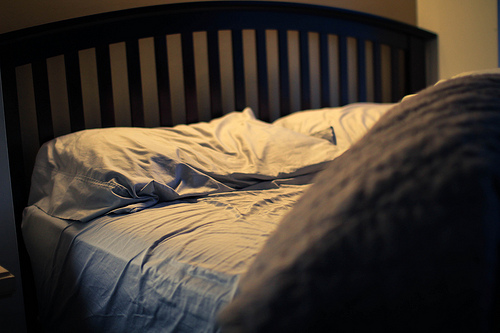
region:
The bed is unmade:
[3, 8, 496, 328]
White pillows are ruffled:
[17, 83, 439, 213]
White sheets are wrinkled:
[20, 179, 361, 323]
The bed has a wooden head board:
[6, 8, 451, 168]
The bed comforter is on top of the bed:
[204, 66, 464, 331]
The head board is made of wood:
[5, 9, 442, 163]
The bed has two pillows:
[22, 74, 474, 179]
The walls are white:
[7, 3, 497, 93]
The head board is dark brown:
[8, 6, 445, 142]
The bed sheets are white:
[17, 175, 374, 317]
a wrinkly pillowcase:
[31, 105, 336, 222]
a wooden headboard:
[4, 0, 448, 149]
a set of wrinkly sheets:
[43, 194, 245, 331]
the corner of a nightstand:
[0, 255, 28, 311]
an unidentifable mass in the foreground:
[251, 177, 496, 327]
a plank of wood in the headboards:
[250, 30, 272, 115]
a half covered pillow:
[280, 97, 419, 174]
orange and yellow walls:
[436, 3, 491, 80]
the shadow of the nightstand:
[21, 239, 73, 326]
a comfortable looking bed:
[9, 119, 466, 331]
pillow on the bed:
[66, 89, 309, 216]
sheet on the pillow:
[80, 105, 286, 241]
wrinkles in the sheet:
[154, 190, 248, 275]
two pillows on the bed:
[93, 90, 373, 222]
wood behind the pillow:
[116, 28, 246, 88]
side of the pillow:
[34, 143, 126, 242]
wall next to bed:
[448, 13, 485, 52]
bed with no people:
[157, 71, 366, 213]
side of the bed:
[48, 243, 161, 320]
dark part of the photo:
[7, 269, 71, 327]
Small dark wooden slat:
[23, 56, 75, 165]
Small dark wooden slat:
[52, 43, 97, 136]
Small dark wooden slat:
[78, 29, 130, 131]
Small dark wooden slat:
[98, 21, 160, 136]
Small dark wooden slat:
[136, 30, 197, 147]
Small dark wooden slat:
[172, 29, 211, 129]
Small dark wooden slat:
[195, 24, 239, 116]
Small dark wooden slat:
[223, 22, 265, 104]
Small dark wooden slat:
[249, 15, 281, 117]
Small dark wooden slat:
[291, 23, 328, 130]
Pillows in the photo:
[154, 130, 266, 176]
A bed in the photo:
[130, 214, 233, 274]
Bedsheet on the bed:
[170, 225, 242, 263]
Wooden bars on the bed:
[160, 42, 325, 91]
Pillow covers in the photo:
[77, 114, 372, 168]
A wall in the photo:
[443, 17, 490, 56]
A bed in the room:
[127, 51, 414, 326]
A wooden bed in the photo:
[137, 64, 287, 307]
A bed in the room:
[193, 102, 333, 209]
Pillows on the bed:
[75, 96, 341, 171]